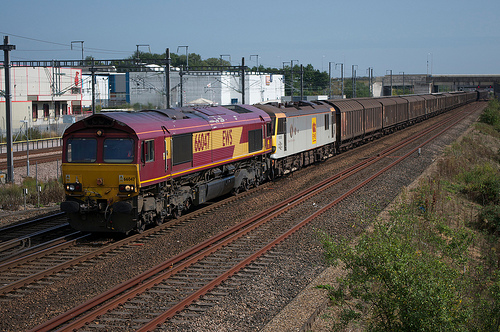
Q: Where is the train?
A: On the tracks.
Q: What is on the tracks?
A: A train.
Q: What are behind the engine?
A: Cars.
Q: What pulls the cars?
A: The engine.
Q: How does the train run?
A: Electricity.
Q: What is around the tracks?
A: Gravel.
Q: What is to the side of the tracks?
A: Plants.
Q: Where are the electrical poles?
A: Behind the train.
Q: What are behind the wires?
A: Buildings.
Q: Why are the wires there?
A: Electricity.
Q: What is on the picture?
A: Red first train engine.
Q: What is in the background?
A: White buildings.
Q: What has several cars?
A: A long train.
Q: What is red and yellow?
A: The engine.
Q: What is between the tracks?
A: Lots of gravel.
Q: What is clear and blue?
A: The sky.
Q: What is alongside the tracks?
A: A bush.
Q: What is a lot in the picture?
A: Wooden poles.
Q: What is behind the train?
A: Some white buildings.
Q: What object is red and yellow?
A: Train engine.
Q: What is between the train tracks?
A: Gravel.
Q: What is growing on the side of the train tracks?
A: Bushes.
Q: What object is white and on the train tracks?
A: A boxcar.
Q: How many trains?
A: 1.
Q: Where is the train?
A: Tracks.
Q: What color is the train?
A: Maroon.